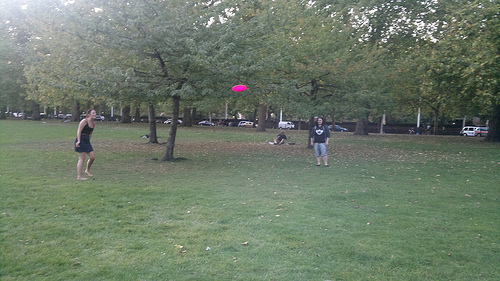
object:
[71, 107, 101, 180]
girl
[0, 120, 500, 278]
grass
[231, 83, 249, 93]
frisbee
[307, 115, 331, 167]
woman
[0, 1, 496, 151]
trees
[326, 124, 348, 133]
car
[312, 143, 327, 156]
shorts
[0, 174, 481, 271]
grass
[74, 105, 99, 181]
woman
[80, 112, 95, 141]
top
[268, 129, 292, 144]
person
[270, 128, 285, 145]
person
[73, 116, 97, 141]
shirt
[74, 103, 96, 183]
person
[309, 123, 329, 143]
shirt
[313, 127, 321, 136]
symbol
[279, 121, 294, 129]
van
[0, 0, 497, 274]
park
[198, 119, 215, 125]
car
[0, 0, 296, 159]
tree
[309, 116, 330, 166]
person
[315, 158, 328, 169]
shoes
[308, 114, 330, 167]
lady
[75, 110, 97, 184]
man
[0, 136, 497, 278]
lawn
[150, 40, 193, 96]
branches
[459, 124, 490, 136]
car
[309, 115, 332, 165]
man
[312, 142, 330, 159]
half-trouser